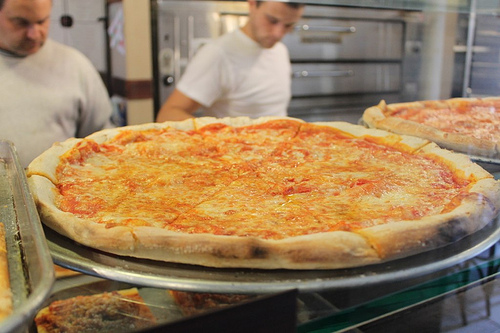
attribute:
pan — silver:
[30, 225, 484, 292]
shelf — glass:
[0, 134, 500, 330]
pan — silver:
[25, 182, 498, 294]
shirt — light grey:
[0, 36, 112, 164]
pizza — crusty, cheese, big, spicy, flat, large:
[29, 114, 499, 269]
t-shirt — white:
[176, 24, 292, 116]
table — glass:
[0, 123, 498, 330]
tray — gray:
[20, 171, 498, 293]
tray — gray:
[34, 200, 498, 295]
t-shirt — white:
[172, 25, 278, 116]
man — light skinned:
[156, 0, 302, 122]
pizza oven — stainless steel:
[216, 5, 415, 115]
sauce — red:
[276, 182, 315, 196]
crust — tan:
[129, 222, 376, 267]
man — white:
[144, 0, 313, 124]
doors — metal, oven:
[224, 7, 403, 99]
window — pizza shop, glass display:
[3, 268, 497, 329]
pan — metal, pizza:
[33, 211, 497, 295]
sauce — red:
[47, 305, 95, 324]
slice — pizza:
[42, 281, 157, 331]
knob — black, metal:
[156, 69, 178, 89]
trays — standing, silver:
[453, 2, 494, 102]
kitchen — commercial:
[5, 0, 495, 330]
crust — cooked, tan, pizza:
[138, 227, 352, 270]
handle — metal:
[295, 66, 362, 80]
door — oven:
[284, 60, 409, 104]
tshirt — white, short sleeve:
[174, 27, 298, 125]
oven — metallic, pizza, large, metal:
[161, 3, 439, 117]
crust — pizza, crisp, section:
[204, 235, 277, 266]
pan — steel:
[1, 131, 61, 330]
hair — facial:
[245, 16, 285, 46]